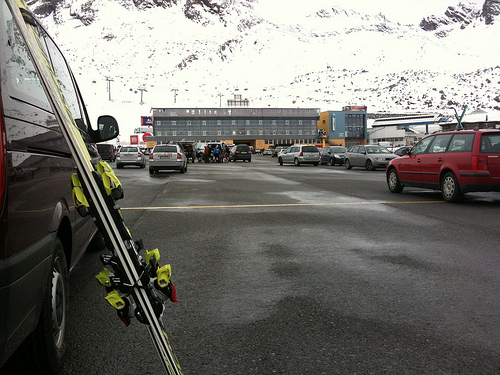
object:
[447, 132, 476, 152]
window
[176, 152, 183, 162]
taillight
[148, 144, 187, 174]
car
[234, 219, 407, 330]
section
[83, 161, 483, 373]
pavement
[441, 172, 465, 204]
tire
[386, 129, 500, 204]
car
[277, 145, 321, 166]
car